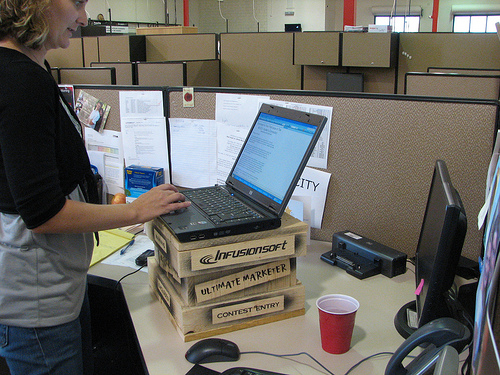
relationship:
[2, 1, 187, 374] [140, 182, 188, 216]
woman has finger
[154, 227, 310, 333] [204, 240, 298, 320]
box has writing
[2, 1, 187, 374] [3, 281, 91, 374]
woman in jeans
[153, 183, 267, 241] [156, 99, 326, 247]
keyboard on laptop